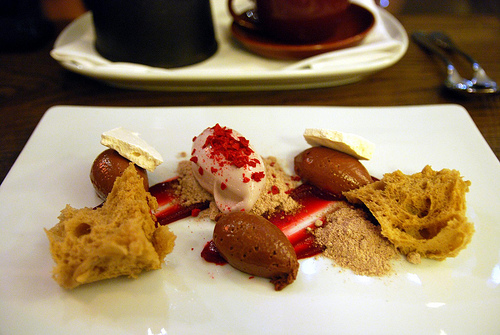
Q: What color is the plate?
A: White.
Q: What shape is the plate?
A: Rectangular.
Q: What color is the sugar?
A: Brown.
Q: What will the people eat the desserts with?
A: Fork and spoon.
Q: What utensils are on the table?
A: Fork and spoon.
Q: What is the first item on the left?
A: Crusty bread.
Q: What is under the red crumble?
A: Cream.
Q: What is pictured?
A: Dessert.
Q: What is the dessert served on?
A: White plate.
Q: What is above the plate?
A: Another plate.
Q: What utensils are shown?
A: Fork and spoon.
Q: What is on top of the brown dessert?
A: White brittle.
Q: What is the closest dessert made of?
A: Chocolate.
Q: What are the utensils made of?
A: Metal.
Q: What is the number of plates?
A: 2.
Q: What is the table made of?
A: Wood.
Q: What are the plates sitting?
A: Table.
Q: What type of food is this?
A: Dessert.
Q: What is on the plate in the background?
A: Coffee cups.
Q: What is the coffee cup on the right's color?
A: Brown.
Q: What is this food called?
A: Pastries.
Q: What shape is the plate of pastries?
A: Square.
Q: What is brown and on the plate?
A: Small chocolate dessert.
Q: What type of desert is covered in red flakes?
A: A small cream dessert.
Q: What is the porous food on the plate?
A: Bread.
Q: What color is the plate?
A: White.